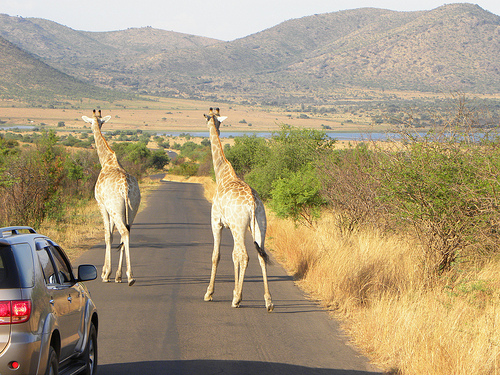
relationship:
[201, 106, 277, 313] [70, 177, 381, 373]
giraffe standing on road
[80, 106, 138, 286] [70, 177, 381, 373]
giraffe standing on road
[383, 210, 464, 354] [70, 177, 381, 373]
grass by road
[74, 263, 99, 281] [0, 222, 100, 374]
mirror of vehicle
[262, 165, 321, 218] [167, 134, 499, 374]
bush in grass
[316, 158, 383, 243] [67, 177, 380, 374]
tree by road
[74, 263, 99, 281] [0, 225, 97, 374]
mirror on side of car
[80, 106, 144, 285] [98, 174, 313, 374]
giraffe on street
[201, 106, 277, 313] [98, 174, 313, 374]
giraffe on street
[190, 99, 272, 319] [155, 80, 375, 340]
giraffe with coat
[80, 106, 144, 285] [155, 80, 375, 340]
giraffe with coat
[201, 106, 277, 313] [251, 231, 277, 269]
giraffe with tuft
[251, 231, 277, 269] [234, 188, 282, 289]
tuft on tail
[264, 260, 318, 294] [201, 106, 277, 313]
shadow of a giraffe